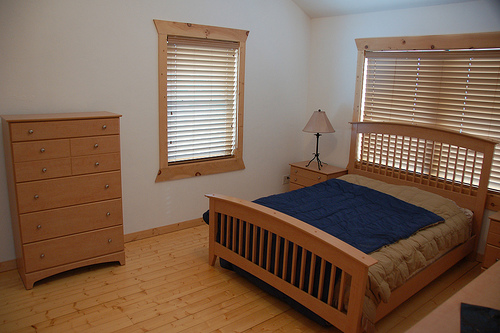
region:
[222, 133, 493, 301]
light brown full bed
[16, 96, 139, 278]
light brown tall dresser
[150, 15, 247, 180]
small light brown trimmed window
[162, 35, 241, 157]
tan window shade in small window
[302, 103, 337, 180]
black and brown lamp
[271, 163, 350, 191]
small brown night stand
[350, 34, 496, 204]
large window trimmed in wood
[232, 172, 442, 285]
blue blanket on the bed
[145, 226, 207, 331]
light brown wood floor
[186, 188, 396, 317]
light brown foot board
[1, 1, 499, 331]
A neat and tidy bedroom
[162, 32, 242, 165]
Blinds over a window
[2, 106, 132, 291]
A brown and wooden dresser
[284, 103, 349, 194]
Lamp on an end table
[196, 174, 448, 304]
Blue blanket on the bed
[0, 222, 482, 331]
A brown wooden floor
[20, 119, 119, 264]
Knobs on the drawers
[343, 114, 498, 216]
Headboard of a bed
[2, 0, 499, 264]
The walls of the room are white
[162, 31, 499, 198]
The blinds are closed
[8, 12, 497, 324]
A very plainly decorated bedroom.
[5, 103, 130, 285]
A tall wooden chest of drawers.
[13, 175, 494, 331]
The floor is covered in light colored wood.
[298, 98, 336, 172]
A small bedside lamp.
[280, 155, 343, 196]
A nightstand made of wood.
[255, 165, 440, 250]
A blue cover on the bed.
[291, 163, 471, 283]
A brown cover under the blue cover.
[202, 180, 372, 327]
The foot board of the bed frame.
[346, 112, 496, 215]
The wood headboard of the bed.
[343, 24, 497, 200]
A large window behind the headboard.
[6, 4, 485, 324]
a clean, sparse bedroom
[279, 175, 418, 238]
a navy blue blanket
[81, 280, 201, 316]
a pine hardwood floor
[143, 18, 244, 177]
a window with closed blinds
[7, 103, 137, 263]
a large chest of drawers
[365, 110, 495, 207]
the headboard of a bed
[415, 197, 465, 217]
a beige comforter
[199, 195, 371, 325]
the footboard of a bed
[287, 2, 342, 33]
the corner of a room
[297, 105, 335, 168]
a bedside lamp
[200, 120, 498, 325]
a wooden bed in the room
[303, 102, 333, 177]
a lamp by the bed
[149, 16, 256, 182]
a wooden window on the wall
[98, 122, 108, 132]
the handle for a drawer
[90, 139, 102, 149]
the handle for a drawer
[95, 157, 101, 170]
the handle for a drawer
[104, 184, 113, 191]
the handle for a drawer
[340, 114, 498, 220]
a wooden head rest for a bed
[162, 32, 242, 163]
a window with white blinds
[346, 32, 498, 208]
a large window with a wooden frame